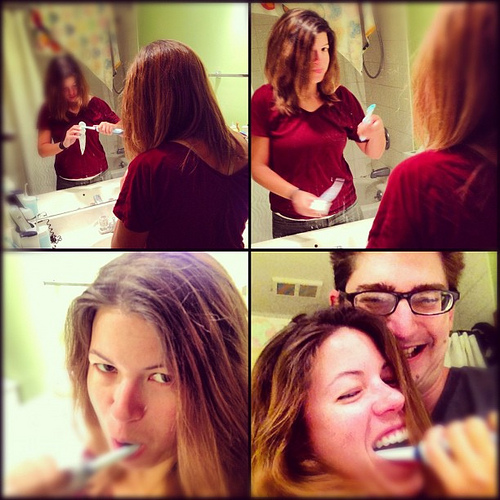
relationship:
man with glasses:
[319, 247, 468, 392] [337, 282, 460, 322]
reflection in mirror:
[29, 45, 124, 182] [1, 4, 122, 196]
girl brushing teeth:
[1, 252, 249, 500] [371, 429, 413, 450]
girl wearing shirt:
[107, 38, 248, 248] [109, 140, 249, 249]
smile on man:
[395, 338, 430, 361] [326, 249, 498, 441]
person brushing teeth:
[195, 20, 420, 284] [385, 424, 413, 444]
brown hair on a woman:
[104, 25, 234, 158] [113, 28, 254, 253]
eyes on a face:
[93, 358, 171, 387] [96, 316, 178, 464]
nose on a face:
[364, 376, 406, 416] [253, 300, 426, 495]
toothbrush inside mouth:
[46, 438, 143, 485] [86, 426, 156, 480]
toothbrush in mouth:
[376, 431, 435, 461] [355, 414, 431, 459]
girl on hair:
[255, 10, 389, 250] [266, 11, 314, 112]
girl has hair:
[255, 311, 437, 498] [252, 303, 438, 495]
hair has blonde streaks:
[252, 303, 438, 495] [255, 367, 297, 476]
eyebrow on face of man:
[353, 280, 397, 296] [326, 249, 498, 441]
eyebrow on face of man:
[408, 282, 449, 293] [326, 249, 498, 441]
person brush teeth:
[248, 293, 500, 500] [371, 418, 411, 448]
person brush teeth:
[258, 293, 429, 495] [370, 425, 418, 452]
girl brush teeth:
[107, 38, 248, 248] [66, 91, 76, 97]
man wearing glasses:
[319, 247, 468, 392] [343, 284, 459, 321]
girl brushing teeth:
[255, 311, 437, 498] [371, 424, 415, 455]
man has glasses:
[319, 247, 468, 392] [338, 287, 461, 317]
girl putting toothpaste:
[32, 45, 127, 170] [77, 120, 91, 151]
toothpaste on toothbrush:
[77, 120, 91, 151] [81, 123, 124, 137]